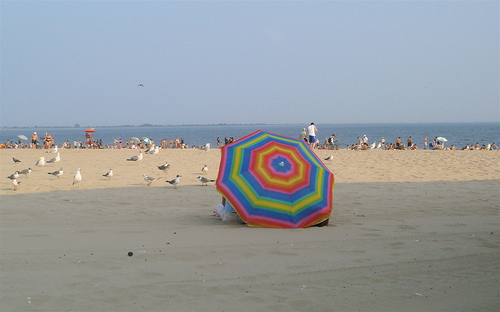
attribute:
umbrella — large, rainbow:
[199, 127, 356, 237]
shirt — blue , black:
[219, 193, 240, 218]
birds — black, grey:
[39, 133, 204, 195]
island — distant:
[95, 117, 202, 141]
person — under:
[222, 195, 239, 226]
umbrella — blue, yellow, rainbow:
[216, 130, 337, 226]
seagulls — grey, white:
[5, 149, 212, 218]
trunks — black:
[28, 139, 38, 144]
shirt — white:
[301, 128, 323, 138]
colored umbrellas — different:
[215, 130, 336, 227]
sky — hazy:
[22, 6, 458, 138]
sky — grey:
[2, 2, 497, 121]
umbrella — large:
[212, 125, 342, 232]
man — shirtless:
[28, 131, 39, 147]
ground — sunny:
[175, 61, 211, 78]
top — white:
[306, 121, 323, 151]